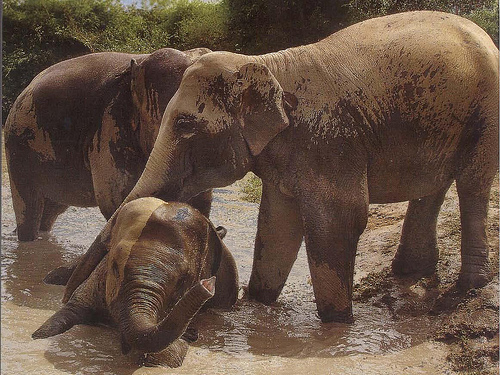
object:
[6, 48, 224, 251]
elephant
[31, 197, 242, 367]
bath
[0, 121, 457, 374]
water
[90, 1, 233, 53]
leaves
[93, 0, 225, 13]
sky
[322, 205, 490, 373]
mud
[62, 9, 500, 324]
elephant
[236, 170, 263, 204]
grass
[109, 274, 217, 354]
trunk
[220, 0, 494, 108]
trees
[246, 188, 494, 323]
four legs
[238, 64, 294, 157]
ear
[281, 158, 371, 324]
leg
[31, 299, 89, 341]
leg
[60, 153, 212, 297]
trunk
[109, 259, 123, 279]
eyes